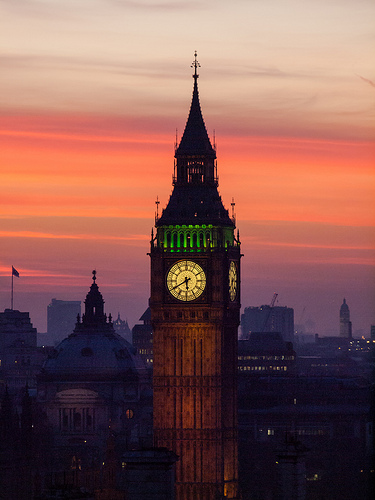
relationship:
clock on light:
[151, 250, 217, 317] [146, 223, 220, 245]